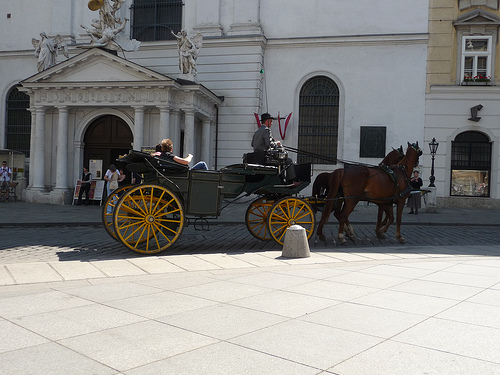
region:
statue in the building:
[171, 22, 209, 88]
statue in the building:
[78, 0, 140, 60]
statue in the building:
[28, 23, 73, 67]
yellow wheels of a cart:
[97, 180, 197, 260]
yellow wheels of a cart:
[236, 197, 318, 249]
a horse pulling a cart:
[318, 140, 428, 243]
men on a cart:
[148, 105, 304, 186]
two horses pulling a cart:
[308, 138, 425, 251]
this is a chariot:
[97, 111, 428, 246]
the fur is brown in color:
[356, 175, 386, 192]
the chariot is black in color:
[193, 175, 215, 205]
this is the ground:
[193, 292, 373, 369]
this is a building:
[293, 17, 403, 144]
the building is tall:
[310, 2, 396, 147]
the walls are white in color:
[383, 88, 396, 104]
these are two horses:
[321, 142, 423, 245]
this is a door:
[88, 128, 118, 160]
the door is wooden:
[93, 121, 107, 142]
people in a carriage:
[100, 7, 281, 261]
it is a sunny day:
[88, 288, 173, 352]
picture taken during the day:
[29, 47, 476, 356]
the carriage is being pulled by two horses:
[89, 99, 494, 257]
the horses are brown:
[303, 120, 493, 309]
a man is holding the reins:
[232, 100, 343, 232]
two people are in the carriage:
[140, 106, 255, 235]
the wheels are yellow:
[88, 166, 202, 266]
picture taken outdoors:
[50, 65, 471, 275]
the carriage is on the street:
[79, 111, 442, 241]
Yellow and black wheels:
[103, 182, 185, 253]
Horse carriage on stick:
[103, 138, 422, 254]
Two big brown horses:
[319, 142, 426, 242]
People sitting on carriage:
[153, 137, 212, 169]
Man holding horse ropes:
[251, 110, 300, 184]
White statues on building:
[10, 1, 235, 73]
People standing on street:
[0, 162, 122, 207]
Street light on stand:
[423, 135, 439, 207]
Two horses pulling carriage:
[102, 108, 436, 250]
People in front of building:
[72, 160, 124, 212]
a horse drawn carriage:
[92, 102, 432, 265]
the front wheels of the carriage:
[244, 192, 317, 258]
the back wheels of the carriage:
[97, 175, 187, 270]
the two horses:
[296, 132, 436, 267]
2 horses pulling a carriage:
[95, 108, 432, 247]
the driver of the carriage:
[250, 104, 300, 193]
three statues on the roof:
[20, 13, 205, 78]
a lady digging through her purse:
[94, 155, 126, 217]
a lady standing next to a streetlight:
[405, 166, 426, 217]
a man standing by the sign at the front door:
[70, 161, 100, 209]